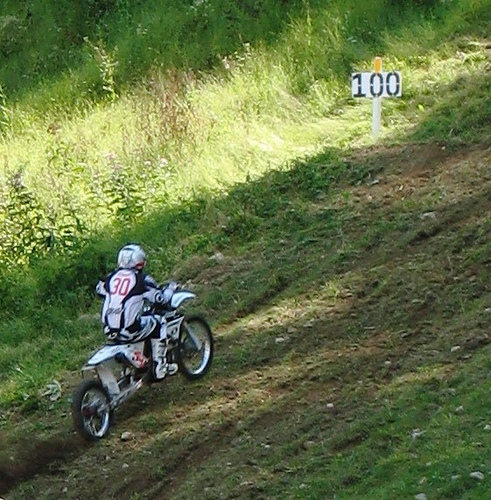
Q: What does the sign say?
A: 100.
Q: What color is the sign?
A: White.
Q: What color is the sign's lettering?
A: Black.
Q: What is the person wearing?
A: Helmet.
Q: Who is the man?
A: Biker.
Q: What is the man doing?
A: Riding bike.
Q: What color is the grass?
A: Green.